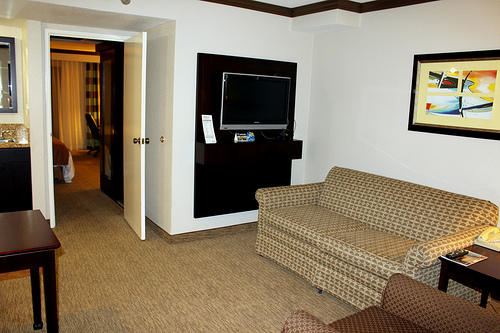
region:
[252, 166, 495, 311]
Sofa with brown pattern.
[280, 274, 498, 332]
Taupe colored armchair.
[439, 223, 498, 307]
Dark brown end table.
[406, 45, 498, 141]
Framed print.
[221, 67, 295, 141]
Television.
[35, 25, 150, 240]
Entrance into bedroom.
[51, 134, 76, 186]
Edge of bed with a red blanket and white sheets showing.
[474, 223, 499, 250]
Telephone.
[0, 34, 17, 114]
Portion of a mirror with a dark brown frame.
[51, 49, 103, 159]
Window covered with white sheers and a plaid curtain.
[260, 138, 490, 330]
a couch inside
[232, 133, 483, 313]
a couch next to the table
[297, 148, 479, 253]
a table next to the couch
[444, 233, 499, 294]
a remote on the table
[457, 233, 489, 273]
a tv remote on the table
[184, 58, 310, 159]
a tv against the wall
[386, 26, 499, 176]
a picture on the wall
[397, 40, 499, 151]
a framed picture on teh wall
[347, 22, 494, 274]
a picture above teh couch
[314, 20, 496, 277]
a framed picture above the couch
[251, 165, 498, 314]
Beige sofa with brown half circles.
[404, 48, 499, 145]
Painting on the wall with dark frame.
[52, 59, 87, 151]
Sheer white curtains hanging at the window.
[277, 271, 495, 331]
Upholstered brown chair near table.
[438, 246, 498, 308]
Dark brown wood end table.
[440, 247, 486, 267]
Magazine on top of end table.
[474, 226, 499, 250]
Beige phone on end table.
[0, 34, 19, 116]
Mirror with silver frame hanging on the wall.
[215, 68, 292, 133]
Black and chrome television on entertainment console.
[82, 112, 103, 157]
Dark chair in the next room.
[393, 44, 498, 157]
a picture on a wall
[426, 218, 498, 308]
end table with phone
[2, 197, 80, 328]
wooden table with 2 legs showing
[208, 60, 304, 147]
tv monito in corner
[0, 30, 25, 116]
partial mirror showing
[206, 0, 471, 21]
ceiling with wood trim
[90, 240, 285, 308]
beige carpet area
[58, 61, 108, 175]
curtains in a far room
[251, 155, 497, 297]
a couch in the living room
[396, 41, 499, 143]
a picture on the wall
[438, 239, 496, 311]
a coffee table next to the couch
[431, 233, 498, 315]
a coffee table between the couch and the chair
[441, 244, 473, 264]
a television controller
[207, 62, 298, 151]
a large HD tv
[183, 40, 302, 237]
a black entertainment center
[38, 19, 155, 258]
a white open door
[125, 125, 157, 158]
to doorknob handles on the door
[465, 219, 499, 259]
a white telephone on the coffee table